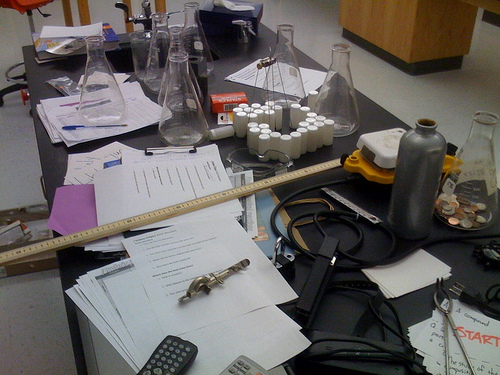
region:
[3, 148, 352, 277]
wooden ruler on table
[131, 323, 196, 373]
black calculator on table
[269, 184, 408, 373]
black cords on table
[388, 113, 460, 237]
silver container on table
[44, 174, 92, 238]
purple paper on table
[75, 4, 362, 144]
glass jars on the table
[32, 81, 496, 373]
white papers on the table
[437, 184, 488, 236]
coins in the glass jar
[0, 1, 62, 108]
red chair on the floor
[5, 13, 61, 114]
base of chair is black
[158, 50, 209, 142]
A clear science beaker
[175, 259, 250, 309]
A metal calc tool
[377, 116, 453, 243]
A small nalgene bottle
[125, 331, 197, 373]
A tv remote control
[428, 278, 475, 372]
Hot stuff tongs for holding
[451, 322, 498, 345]
Red ink on paper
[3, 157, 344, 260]
A long yard stick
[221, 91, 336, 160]
Many small white bottles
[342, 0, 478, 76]
The bottom of desk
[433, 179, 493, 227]
Change at bottom of jar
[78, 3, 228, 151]
Chemistry Beakers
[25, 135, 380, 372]
Desk cluttered with paper and implements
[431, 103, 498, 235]
Beaker full of coins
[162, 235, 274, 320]
a compass on paper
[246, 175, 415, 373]
A power cord on a desk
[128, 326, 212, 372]
A calculator on a desk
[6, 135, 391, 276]
A yardstick among papers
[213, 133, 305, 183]
safety glasses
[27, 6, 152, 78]
textbook on the edge of a table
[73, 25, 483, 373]
science lab table cluttered with tools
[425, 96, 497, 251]
a glass container on the table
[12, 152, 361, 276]
a ruler on top of papers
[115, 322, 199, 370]
a remote on top of the papers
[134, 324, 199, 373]
the remote is black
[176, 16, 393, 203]
the table is black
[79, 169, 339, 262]
the ruler is beige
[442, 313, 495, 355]
red letters on the paper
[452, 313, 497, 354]
the word is start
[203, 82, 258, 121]
a red box on the table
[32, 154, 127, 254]
a piece of purple paper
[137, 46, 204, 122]
these are beakers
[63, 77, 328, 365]
this is a chemistry classroom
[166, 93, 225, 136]
the beakers are glass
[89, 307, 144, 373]
this is a remote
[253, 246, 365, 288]
this is a cable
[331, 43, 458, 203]
this is a bottle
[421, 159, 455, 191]
the bottle is grey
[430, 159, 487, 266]
the bottle is metal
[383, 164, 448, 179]
the beaker has coins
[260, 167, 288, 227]
this is a rule